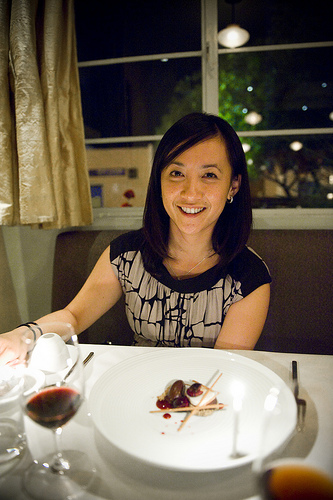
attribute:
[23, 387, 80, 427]
wine — red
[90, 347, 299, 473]
plate — small, white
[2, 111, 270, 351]
woman — smiling, sitting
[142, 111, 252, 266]
hair — black, resting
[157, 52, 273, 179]
tree — green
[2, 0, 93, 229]
curtain — brown, gold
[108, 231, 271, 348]
blouse — black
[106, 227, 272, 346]
top — black